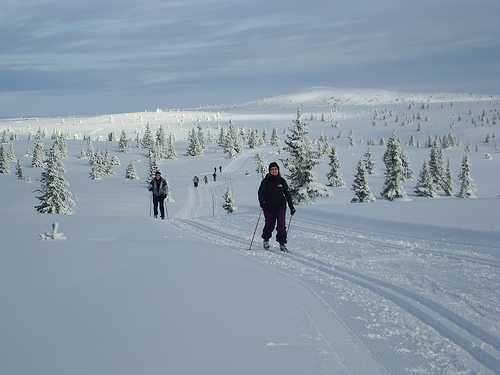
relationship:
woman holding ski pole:
[258, 161, 296, 252] [249, 200, 266, 252]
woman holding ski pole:
[258, 161, 296, 252] [285, 208, 294, 233]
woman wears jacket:
[258, 161, 296, 252] [258, 173, 294, 209]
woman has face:
[258, 161, 296, 252] [271, 167, 279, 176]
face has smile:
[271, 167, 279, 176] [271, 170, 276, 173]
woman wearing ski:
[258, 161, 296, 252] [275, 246, 293, 256]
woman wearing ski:
[258, 161, 296, 252] [257, 243, 279, 256]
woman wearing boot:
[258, 161, 296, 252] [264, 239, 269, 249]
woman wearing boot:
[258, 161, 296, 252] [279, 241, 286, 251]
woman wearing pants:
[258, 161, 296, 252] [260, 209, 287, 244]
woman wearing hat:
[258, 161, 296, 252] [269, 163, 280, 171]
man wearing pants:
[148, 171, 168, 220] [152, 195, 165, 219]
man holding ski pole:
[148, 171, 168, 220] [149, 191, 154, 219]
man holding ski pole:
[148, 171, 168, 220] [164, 199, 169, 220]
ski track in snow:
[175, 215, 498, 374] [1, 87, 499, 373]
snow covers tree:
[350, 159, 376, 202] [351, 157, 376, 203]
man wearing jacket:
[148, 171, 168, 220] [148, 177, 170, 198]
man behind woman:
[148, 171, 168, 220] [258, 161, 296, 252]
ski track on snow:
[175, 215, 498, 374] [1, 87, 499, 373]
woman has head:
[258, 161, 296, 252] [268, 162, 279, 177]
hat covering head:
[269, 163, 280, 171] [268, 162, 279, 177]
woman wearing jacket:
[258, 161, 296, 252] [258, 173, 294, 209]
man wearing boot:
[148, 171, 168, 220] [159, 214, 165, 221]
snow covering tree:
[32, 141, 82, 217] [34, 143, 75, 216]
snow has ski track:
[1, 87, 499, 373] [175, 215, 498, 374]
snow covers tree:
[455, 158, 478, 199] [456, 153, 478, 198]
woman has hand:
[258, 161, 296, 252] [289, 206, 295, 215]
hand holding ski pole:
[289, 206, 295, 215] [285, 208, 294, 233]